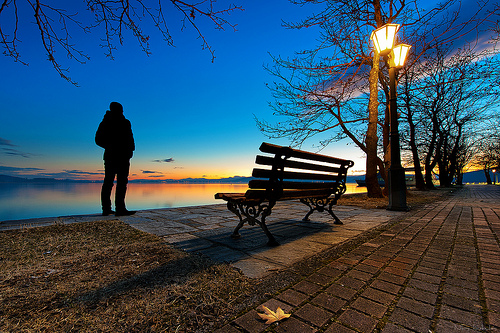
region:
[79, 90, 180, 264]
This is a person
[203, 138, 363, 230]
the bench is empty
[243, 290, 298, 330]
a maple leaf on the ground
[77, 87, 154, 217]
a man standing by the bay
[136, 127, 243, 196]
sunset is visible on horizon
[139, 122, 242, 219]
a blue, yellow, and orange sky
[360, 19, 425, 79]
the lamps are yellow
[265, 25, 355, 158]
the trees are bare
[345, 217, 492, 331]
the walkway is made of bricks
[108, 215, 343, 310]
shadow on the ground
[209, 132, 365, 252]
bench is overlooking the water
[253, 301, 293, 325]
a leaf on the ground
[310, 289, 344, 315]
a brown paving brick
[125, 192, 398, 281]
a concrete pad under a bench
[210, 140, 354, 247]
a wooden bench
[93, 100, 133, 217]
a person standing next to water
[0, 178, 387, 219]
water in front of a person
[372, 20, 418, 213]
a double headed light pole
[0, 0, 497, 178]
a sky at sunrise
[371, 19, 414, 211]
Light up street lights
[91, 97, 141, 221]
A person standing near water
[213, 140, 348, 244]
An empty park bench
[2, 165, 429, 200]
A body of water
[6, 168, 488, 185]
Land on the horizon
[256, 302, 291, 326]
Leaf on the ground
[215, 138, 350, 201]
A wooden park bench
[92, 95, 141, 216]
A person standing up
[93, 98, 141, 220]
A person's silhouette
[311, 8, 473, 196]
Trees lining park paths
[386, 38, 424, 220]
The streetlamp is on.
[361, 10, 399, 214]
The streetlamp is on.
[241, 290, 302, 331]
The leaf is brown.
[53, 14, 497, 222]
The man is looking off into the horizon.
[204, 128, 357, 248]
The bench is empty.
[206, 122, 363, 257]
The bench is vacant.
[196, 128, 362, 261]
The bench is available.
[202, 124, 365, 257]
The bench is unoccupied.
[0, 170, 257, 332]
The grass is brown.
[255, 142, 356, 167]
wood slat on the park bench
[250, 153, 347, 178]
wood slat on the park bench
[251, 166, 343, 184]
wood slat on the park bench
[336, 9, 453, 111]
Street lamps behind the bench in the park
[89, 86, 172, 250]
Woman with a coat and a hat on the edge of the water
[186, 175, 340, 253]
Metal feet support the wooden bench in the park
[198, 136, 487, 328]
Pavered sidewalk next to the bench in the park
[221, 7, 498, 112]
Long slim cloud in the night sky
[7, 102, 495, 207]
Sunset seen in the horizon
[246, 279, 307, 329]
Single leaf on the ground behind the bench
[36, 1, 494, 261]
Trees have no leaves, and the nights are cold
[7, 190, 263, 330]
Brown grass to the left of the bench